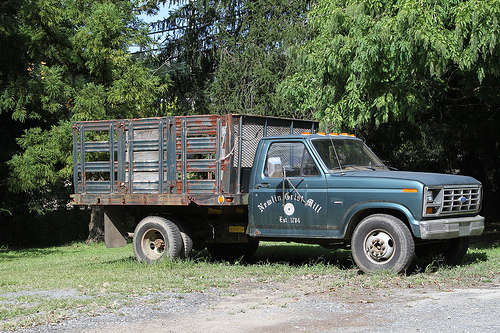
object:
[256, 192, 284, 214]
newlin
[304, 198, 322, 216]
mill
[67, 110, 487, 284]
truck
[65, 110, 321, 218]
bed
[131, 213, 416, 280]
tires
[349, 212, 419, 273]
bald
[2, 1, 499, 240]
trees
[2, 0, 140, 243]
tree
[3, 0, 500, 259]
background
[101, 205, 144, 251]
flaps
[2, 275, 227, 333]
gravel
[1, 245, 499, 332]
foreground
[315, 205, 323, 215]
letters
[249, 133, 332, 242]
door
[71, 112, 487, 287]
parked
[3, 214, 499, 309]
grass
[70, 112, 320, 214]
back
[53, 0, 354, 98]
covered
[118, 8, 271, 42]
lines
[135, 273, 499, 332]
dirt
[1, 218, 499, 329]
ground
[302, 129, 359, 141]
lights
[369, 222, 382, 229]
black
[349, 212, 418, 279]
tire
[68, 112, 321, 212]
trailer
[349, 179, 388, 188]
green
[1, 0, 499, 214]
leaves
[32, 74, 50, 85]
flowers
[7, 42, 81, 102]
branch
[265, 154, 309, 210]
side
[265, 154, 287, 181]
mirror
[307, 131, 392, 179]
windshield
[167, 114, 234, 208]
rusty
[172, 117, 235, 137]
railing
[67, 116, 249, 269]
rear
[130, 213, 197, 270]
tires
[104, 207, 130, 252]
faded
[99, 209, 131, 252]
mudflap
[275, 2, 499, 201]
tree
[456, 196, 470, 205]
logo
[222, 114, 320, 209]
front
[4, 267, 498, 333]
road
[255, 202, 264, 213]
lettering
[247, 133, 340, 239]
side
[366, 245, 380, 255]
bolts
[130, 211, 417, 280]
wheels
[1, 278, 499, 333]
area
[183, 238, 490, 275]
shadow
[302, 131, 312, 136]
yellow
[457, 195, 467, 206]
blue